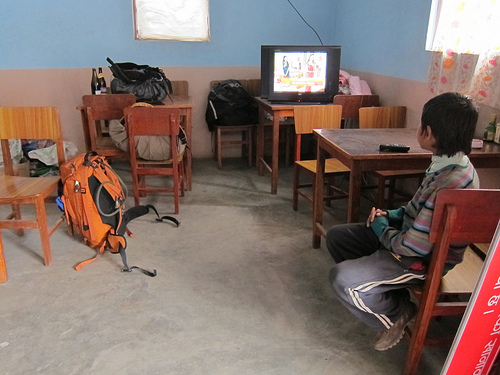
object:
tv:
[260, 43, 341, 104]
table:
[253, 97, 369, 195]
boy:
[325, 92, 479, 354]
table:
[312, 126, 498, 250]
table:
[76, 91, 195, 193]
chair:
[122, 105, 186, 215]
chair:
[0, 105, 66, 268]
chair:
[81, 91, 138, 174]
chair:
[292, 105, 351, 213]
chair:
[357, 105, 425, 211]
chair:
[401, 188, 500, 374]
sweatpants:
[318, 223, 456, 334]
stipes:
[352, 275, 428, 328]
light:
[430, 6, 498, 72]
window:
[422, 1, 499, 61]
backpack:
[104, 55, 175, 107]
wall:
[6, 2, 337, 159]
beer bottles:
[90, 67, 101, 95]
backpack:
[55, 150, 182, 278]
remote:
[377, 142, 412, 153]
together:
[365, 207, 388, 231]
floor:
[2, 156, 500, 373]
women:
[302, 53, 319, 94]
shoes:
[372, 301, 420, 353]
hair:
[419, 93, 478, 162]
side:
[342, 0, 499, 375]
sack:
[104, 101, 192, 162]